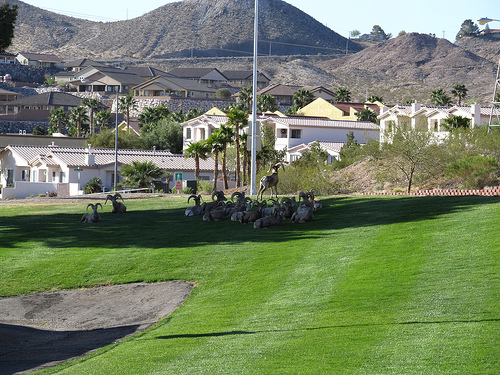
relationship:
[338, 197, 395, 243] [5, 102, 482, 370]
grass on golf course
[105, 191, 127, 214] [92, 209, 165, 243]
animal sitting in grass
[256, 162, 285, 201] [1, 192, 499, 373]
animals on a golf course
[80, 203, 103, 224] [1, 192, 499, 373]
animal on a golf course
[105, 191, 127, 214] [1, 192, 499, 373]
animal on a golf course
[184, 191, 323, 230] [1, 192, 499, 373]
animals on a golf course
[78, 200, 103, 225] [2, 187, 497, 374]
animal in field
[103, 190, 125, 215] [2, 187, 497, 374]
animal in field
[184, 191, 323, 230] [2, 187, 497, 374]
animals in field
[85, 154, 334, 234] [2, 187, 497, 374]
animals laying in field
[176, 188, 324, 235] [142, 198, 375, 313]
animals laying in grass field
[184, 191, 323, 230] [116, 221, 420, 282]
animals laying in grass field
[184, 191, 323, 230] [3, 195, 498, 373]
animals sitting in grass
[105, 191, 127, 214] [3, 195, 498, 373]
animal sitting in grass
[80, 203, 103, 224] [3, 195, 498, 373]
animal sitting in grass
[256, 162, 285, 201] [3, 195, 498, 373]
animals sitting in grass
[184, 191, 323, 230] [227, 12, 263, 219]
animals sitting by pole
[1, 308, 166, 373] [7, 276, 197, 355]
shadow in sand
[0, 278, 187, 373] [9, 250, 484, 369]
road leads to yard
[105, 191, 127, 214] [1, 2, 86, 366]
animal on left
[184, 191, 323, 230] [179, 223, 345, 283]
animals grazing in grass field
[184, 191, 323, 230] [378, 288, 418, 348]
animals sitting in grass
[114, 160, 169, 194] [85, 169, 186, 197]
palm bushes in corner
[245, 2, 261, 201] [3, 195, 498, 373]
pole in grass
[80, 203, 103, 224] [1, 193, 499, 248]
animal in shade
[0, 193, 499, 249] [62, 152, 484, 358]
shade in grass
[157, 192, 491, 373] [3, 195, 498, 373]
line in grass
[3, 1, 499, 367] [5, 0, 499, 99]
view of mountain